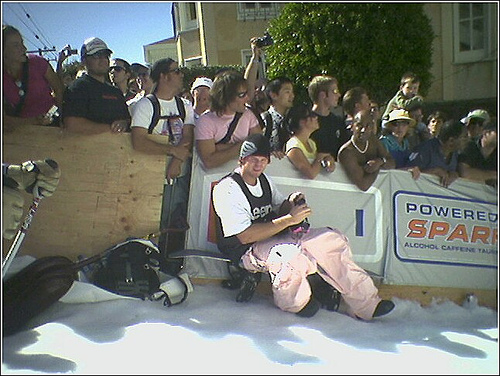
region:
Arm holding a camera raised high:
[244, 30, 277, 102]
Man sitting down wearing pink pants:
[213, 135, 398, 330]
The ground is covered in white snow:
[1, 252, 497, 372]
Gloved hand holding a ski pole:
[0, 151, 64, 285]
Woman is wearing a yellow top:
[283, 100, 335, 179]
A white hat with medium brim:
[384, 108, 416, 128]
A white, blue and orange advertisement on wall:
[383, 166, 498, 301]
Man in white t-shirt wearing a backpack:
[130, 54, 196, 183]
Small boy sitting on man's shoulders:
[378, 69, 425, 131]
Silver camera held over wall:
[38, 101, 68, 133]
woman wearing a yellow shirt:
[284, 109, 331, 176]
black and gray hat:
[227, 133, 279, 153]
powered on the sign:
[399, 197, 493, 221]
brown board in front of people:
[73, 163, 133, 222]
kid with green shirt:
[386, 66, 433, 106]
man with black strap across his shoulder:
[193, 73, 263, 138]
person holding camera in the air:
[242, 32, 283, 50]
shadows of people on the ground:
[229, 309, 311, 371]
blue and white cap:
[73, 34, 115, 56]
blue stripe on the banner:
[350, 201, 366, 240]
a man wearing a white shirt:
[124, 49, 214, 156]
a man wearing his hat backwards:
[131, 51, 219, 169]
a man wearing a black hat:
[218, 131, 319, 257]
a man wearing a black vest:
[196, 129, 336, 281]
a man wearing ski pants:
[198, 138, 383, 313]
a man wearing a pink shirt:
[192, 63, 269, 175]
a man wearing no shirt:
[312, 95, 394, 172]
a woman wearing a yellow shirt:
[272, 98, 329, 173]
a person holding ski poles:
[0, 141, 61, 290]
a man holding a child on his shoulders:
[381, 54, 451, 163]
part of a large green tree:
[253, 8, 434, 107]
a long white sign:
[185, 140, 499, 295]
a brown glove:
[6, 157, 63, 198]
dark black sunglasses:
[172, 63, 185, 78]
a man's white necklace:
[350, 136, 372, 153]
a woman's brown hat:
[387, 107, 415, 124]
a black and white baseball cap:
[233, 133, 271, 164]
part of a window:
[455, 2, 487, 49]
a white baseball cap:
[76, 35, 115, 59]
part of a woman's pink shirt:
[4, 53, 59, 117]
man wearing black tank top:
[215, 143, 382, 312]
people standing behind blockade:
[20, 27, 497, 171]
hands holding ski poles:
[7, 154, 56, 233]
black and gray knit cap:
[237, 135, 270, 160]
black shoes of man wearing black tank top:
[299, 299, 406, 329]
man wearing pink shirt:
[192, 71, 257, 147]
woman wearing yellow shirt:
[283, 103, 325, 175]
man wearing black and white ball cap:
[65, 35, 126, 134]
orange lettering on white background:
[401, 218, 491, 251]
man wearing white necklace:
[345, 110, 377, 190]